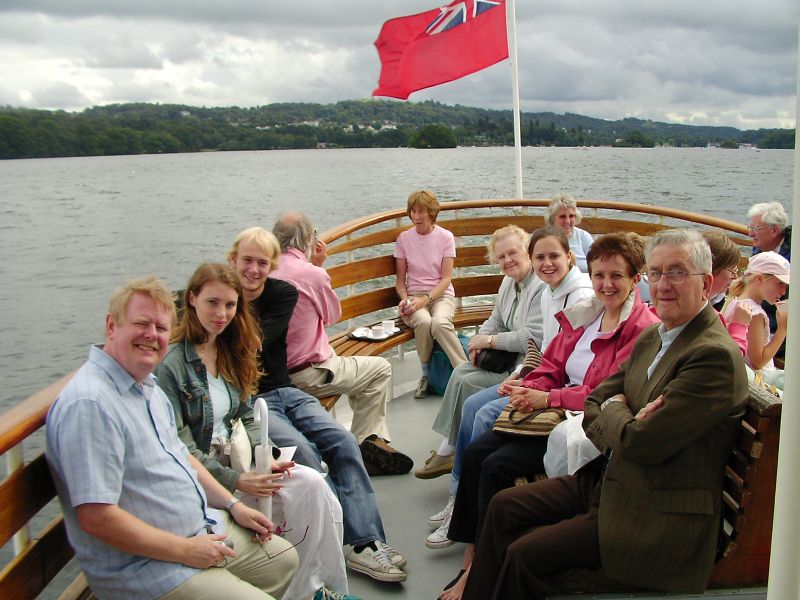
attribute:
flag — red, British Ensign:
[365, 0, 503, 106]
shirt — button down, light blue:
[42, 341, 234, 597]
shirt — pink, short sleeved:
[391, 221, 457, 301]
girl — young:
[714, 251, 775, 384]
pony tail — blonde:
[721, 276, 750, 300]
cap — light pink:
[743, 248, 775, 277]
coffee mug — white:
[369, 325, 386, 336]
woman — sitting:
[391, 188, 469, 398]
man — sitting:
[268, 211, 413, 477]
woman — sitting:
[156, 259, 349, 597]